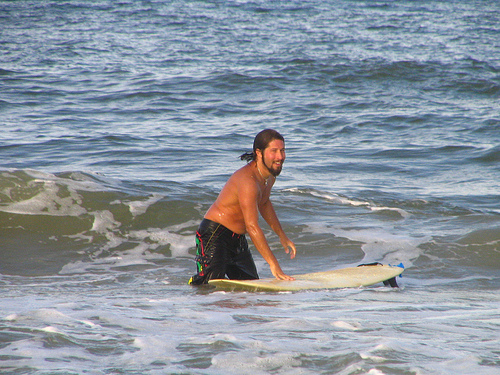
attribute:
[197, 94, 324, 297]
man — smiling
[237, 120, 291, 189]
man — smiling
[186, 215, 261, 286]
bathing suit — black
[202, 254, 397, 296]
surfboard — white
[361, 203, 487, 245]
water — white, foamy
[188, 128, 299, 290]
man — brown haired, surfing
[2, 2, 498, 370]
water — foamy, blue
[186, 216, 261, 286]
trunks — black